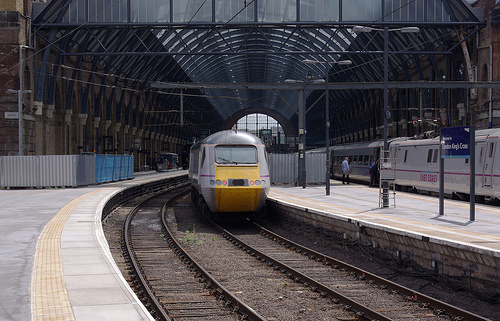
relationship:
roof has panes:
[153, 13, 367, 126] [215, 26, 299, 63]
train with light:
[196, 117, 273, 205] [236, 169, 267, 190]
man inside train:
[330, 146, 360, 191] [196, 117, 273, 205]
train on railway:
[196, 117, 273, 205] [198, 214, 284, 259]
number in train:
[208, 160, 274, 185] [196, 117, 273, 205]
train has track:
[196, 117, 273, 205] [93, 202, 198, 271]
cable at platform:
[183, 87, 231, 113] [90, 105, 198, 239]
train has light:
[196, 117, 273, 205] [236, 169, 267, 190]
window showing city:
[225, 113, 288, 152] [10, 24, 499, 270]